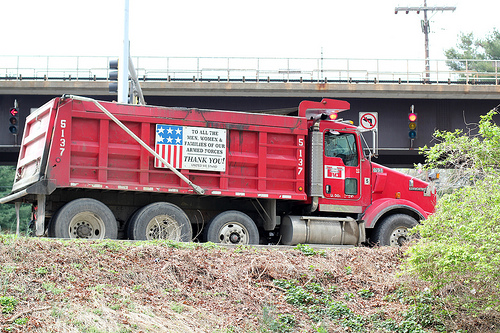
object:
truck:
[1, 99, 438, 247]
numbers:
[295, 137, 305, 180]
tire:
[52, 197, 122, 238]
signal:
[407, 112, 421, 143]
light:
[406, 111, 417, 122]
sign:
[360, 110, 380, 133]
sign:
[152, 122, 228, 173]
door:
[320, 126, 366, 202]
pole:
[116, 0, 134, 103]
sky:
[0, 2, 500, 81]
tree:
[444, 24, 500, 82]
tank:
[276, 213, 363, 248]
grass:
[1, 236, 419, 333]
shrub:
[400, 103, 500, 332]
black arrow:
[361, 115, 372, 127]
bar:
[61, 91, 209, 197]